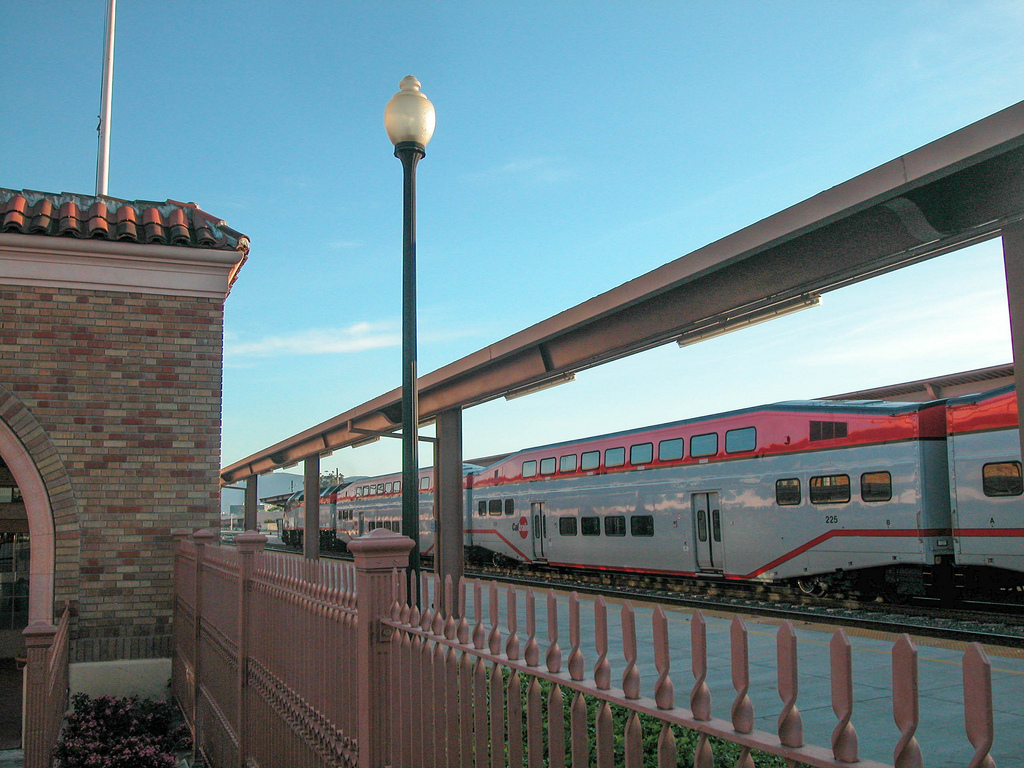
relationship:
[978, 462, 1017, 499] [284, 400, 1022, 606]
window on train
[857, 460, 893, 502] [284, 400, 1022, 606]
window on train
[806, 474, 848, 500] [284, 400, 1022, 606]
window on train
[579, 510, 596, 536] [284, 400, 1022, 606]
window on train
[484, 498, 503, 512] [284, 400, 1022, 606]
window on train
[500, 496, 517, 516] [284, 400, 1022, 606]
window on train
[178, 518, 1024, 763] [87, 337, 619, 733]
fence beside train depot